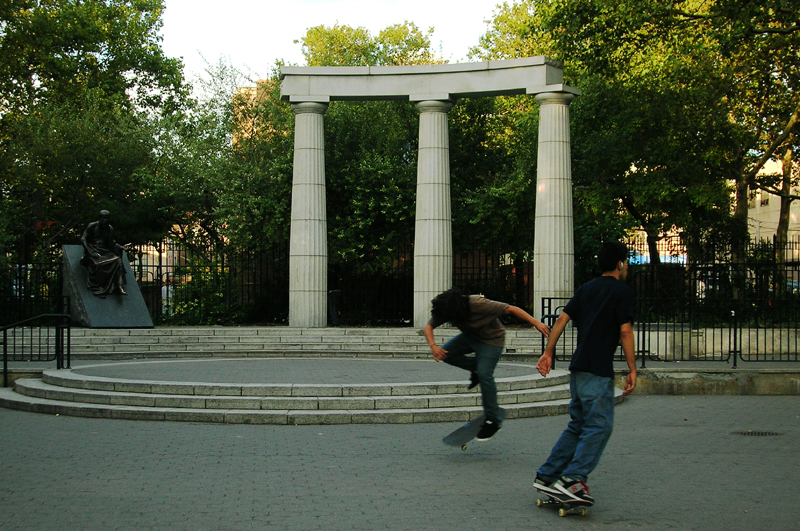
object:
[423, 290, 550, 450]
skater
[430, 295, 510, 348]
shirt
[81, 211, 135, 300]
statue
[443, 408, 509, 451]
skateboard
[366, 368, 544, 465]
air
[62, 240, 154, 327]
monument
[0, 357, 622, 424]
steps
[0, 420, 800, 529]
concrete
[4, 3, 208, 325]
trees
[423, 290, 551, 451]
boy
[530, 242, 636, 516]
boy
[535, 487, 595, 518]
skateboard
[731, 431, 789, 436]
hole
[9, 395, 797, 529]
ground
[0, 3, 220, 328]
tree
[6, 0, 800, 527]
city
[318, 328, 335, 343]
brick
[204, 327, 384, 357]
wall